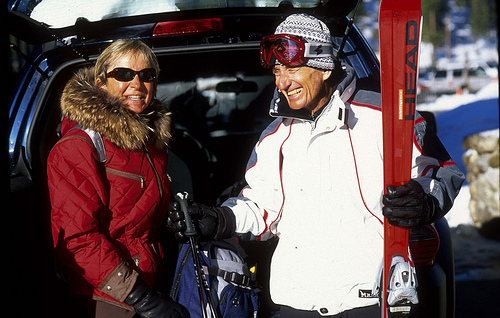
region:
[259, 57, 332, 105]
Man with a big smile on his face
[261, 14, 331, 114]
Man with red ski mask on his head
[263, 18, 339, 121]
Man with a grey hat on his head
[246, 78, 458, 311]
Man with white and red coat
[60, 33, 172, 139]
Woman with sun glasses on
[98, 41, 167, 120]
Blond woman with short hair smiling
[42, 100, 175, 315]
Woman with red furry coat on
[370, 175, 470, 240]
Man wearing black bulky gloves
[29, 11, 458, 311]
Couple standing behind a car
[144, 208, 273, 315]
Blue backpack with black buckles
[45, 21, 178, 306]
this is a person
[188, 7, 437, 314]
this is a person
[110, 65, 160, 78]
this is a pair of glasses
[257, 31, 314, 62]
this is a pair of glasses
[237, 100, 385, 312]
this is a white jacket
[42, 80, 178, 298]
this is a white jacket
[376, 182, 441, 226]
this is a hand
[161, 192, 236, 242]
this is a hand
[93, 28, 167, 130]
the lady is smiling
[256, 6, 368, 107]
the man is smiling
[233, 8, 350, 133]
head of a person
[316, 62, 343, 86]
ear of a person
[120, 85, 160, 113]
smile of a person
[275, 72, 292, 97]
nose of a person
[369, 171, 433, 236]
hand of a person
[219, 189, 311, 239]
arm of a person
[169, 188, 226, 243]
hand of a person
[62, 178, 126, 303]
arm of a person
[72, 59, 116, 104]
ear of a person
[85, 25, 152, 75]
hair of a person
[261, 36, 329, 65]
red and grey goggles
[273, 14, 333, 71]
grey knit hat on head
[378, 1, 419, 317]
red skis in hand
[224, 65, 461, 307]
white and red jacket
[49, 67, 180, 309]
red padded winter jacket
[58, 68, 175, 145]
brown fur on jacket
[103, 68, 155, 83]
black sunglasses on face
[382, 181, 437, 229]
black padded winter glove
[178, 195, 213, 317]
black metal ski pole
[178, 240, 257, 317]
grey and blue back pack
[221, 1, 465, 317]
Man holding red snow skis.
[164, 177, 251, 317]
Man holding ski poles in hand.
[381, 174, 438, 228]
Man wearing black glove on hand.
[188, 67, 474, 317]
Man dressed in white and red jacket.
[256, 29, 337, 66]
Man wearing ged goggles around head.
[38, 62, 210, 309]
Woman dressed in red jacket with fur collar.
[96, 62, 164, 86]
Woman wearing sunglasses over eyes.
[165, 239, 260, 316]
Woman holding blue backpack.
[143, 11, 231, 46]
Rear break light at top of car.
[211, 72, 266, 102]
Rear view mirror inside car.